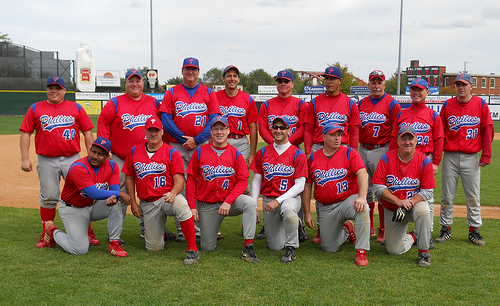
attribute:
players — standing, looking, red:
[39, 47, 494, 265]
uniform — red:
[309, 97, 362, 141]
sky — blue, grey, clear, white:
[214, 1, 306, 53]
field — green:
[126, 243, 396, 302]